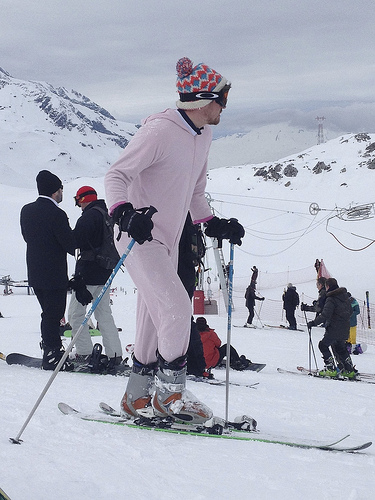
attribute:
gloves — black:
[111, 202, 254, 255]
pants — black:
[36, 281, 67, 371]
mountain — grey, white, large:
[3, 66, 110, 177]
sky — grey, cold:
[30, 34, 144, 82]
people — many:
[25, 79, 373, 361]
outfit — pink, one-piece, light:
[116, 115, 214, 385]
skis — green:
[51, 392, 372, 459]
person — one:
[190, 310, 259, 374]